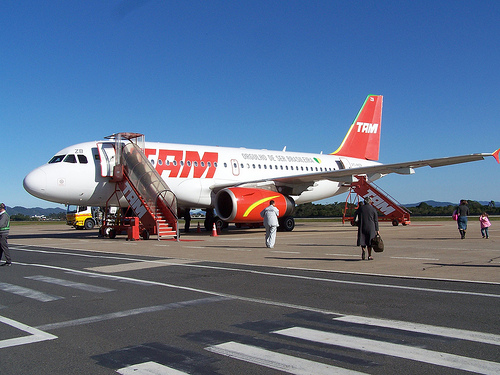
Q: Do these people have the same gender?
A: No, they are both male and female.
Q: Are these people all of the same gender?
A: No, they are both male and female.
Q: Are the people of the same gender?
A: No, they are both male and female.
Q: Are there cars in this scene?
A: No, there are no cars.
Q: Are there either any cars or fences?
A: No, there are no cars or fences.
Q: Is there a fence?
A: No, there are no fences.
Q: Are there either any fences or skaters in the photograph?
A: No, there are no fences or skaters.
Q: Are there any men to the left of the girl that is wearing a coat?
A: Yes, there is a man to the left of the girl.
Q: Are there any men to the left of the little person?
A: Yes, there is a man to the left of the girl.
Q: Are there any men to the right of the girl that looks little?
A: No, the man is to the left of the girl.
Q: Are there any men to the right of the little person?
A: No, the man is to the left of the girl.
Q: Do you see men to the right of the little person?
A: No, the man is to the left of the girl.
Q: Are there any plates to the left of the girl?
A: No, there is a man to the left of the girl.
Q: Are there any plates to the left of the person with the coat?
A: No, there is a man to the left of the girl.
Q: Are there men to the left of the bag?
A: Yes, there is a man to the left of the bag.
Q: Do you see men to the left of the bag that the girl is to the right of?
A: Yes, there is a man to the left of the bag.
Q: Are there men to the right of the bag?
A: No, the man is to the left of the bag.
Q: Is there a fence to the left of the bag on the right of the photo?
A: No, there is a man to the left of the bag.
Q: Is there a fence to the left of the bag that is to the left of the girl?
A: No, there is a man to the left of the bag.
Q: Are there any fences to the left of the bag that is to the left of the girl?
A: No, there is a man to the left of the bag.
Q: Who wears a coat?
A: The man wears a coat.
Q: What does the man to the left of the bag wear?
A: The man wears a coat.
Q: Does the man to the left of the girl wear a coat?
A: Yes, the man wears a coat.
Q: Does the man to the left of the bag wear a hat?
A: No, the man wears a coat.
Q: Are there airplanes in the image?
A: Yes, there is an airplane.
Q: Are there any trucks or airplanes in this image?
A: Yes, there is an airplane.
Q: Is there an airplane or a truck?
A: Yes, there is an airplane.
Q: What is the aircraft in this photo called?
A: The aircraft is an airplane.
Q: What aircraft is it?
A: The aircraft is an airplane.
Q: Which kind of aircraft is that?
A: This is an airplane.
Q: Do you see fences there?
A: No, there are no fences.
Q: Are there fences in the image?
A: No, there are no fences.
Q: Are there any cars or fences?
A: No, there are no fences or cars.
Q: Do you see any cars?
A: No, there are no cars.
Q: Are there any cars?
A: No, there are no cars.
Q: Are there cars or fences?
A: No, there are no cars or fences.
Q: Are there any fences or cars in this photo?
A: No, there are no cars or fences.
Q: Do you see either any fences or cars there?
A: No, there are no cars or fences.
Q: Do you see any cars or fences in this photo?
A: No, there are no cars or fences.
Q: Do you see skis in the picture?
A: No, there are no skis.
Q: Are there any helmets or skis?
A: No, there are no skis or helmets.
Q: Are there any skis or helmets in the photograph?
A: No, there are no skis or helmets.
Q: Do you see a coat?
A: Yes, there is a coat.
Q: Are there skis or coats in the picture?
A: Yes, there is a coat.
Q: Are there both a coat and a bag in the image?
A: Yes, there are both a coat and a bag.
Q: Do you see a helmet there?
A: No, there are no helmets.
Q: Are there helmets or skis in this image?
A: No, there are no helmets or skis.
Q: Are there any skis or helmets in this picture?
A: No, there are no helmets or skis.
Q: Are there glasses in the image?
A: No, there are no glasses.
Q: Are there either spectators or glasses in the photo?
A: No, there are no glasses or spectators.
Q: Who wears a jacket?
A: The man wears a jacket.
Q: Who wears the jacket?
A: The man wears a jacket.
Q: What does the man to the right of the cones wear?
A: The man wears a jacket.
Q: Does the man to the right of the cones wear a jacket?
A: Yes, the man wears a jacket.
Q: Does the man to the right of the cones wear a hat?
A: No, the man wears a jacket.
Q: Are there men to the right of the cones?
A: Yes, there is a man to the right of the cones.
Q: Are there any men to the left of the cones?
A: No, the man is to the right of the cones.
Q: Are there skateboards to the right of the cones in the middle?
A: No, there is a man to the right of the cones.